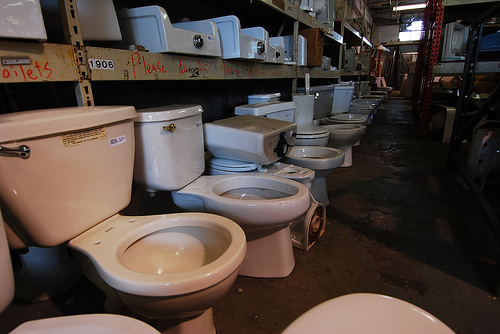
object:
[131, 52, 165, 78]
word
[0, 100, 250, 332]
toilette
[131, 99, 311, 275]
toilette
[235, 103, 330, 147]
toilette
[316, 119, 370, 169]
toilette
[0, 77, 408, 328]
toilets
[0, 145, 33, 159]
handle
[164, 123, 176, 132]
handle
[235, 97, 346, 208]
toilet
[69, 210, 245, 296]
seat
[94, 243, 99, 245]
holes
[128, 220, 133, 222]
holes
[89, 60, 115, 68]
numbers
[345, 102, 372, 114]
toilet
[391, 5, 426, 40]
window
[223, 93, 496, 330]
dirty concrete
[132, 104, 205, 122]
lid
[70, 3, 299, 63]
shelving merchandise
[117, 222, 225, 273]
bowl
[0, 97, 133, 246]
tank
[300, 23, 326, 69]
box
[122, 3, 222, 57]
toilet part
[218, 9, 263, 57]
toilet part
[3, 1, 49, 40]
toilet part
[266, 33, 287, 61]
toilet part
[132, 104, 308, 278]
toilet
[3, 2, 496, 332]
warehouse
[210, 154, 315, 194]
toilet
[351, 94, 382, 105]
toilet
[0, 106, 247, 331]
toilet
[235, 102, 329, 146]
toilet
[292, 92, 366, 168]
toilet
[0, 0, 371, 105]
shelf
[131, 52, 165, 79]
orange letters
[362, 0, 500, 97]
wall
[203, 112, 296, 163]
tank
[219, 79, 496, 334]
floor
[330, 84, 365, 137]
toilet